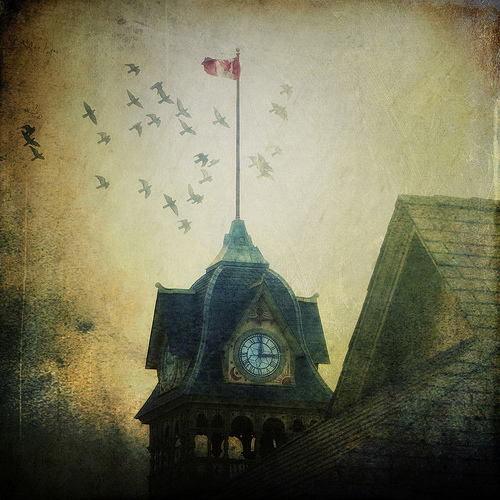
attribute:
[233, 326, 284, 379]
clock — white, big, round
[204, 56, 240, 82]
flag — waving, high, flying, waving left, red, white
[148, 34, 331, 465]
tower — high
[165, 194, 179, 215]
bird — in sky, large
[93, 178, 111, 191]
bird — flying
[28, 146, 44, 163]
bird — flying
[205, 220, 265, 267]
roof — triangle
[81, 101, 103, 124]
bird — flying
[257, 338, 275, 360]
hands — black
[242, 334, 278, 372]
face — white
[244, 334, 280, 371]
numbers — black